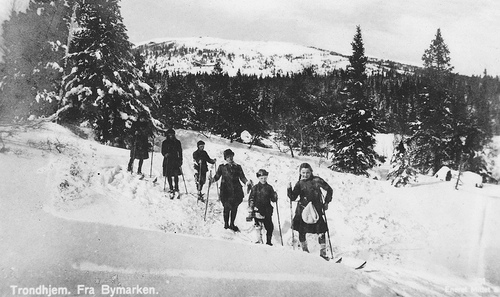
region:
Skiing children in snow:
[127, 110, 342, 258]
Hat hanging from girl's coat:
[300, 203, 317, 224]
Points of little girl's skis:
[327, 256, 369, 268]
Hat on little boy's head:
[252, 168, 272, 178]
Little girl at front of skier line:
[288, 164, 341, 256]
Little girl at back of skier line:
[122, 107, 151, 180]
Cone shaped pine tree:
[330, 24, 382, 180]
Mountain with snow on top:
[137, 40, 440, 131]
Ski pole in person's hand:
[203, 166, 215, 219]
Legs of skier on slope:
[221, 205, 238, 229]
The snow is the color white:
[352, 178, 451, 263]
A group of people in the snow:
[108, 102, 379, 259]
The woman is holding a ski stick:
[281, 177, 305, 246]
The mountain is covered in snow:
[141, 18, 356, 80]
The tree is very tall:
[2, 0, 155, 145]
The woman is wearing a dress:
[282, 158, 338, 242]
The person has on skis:
[120, 163, 165, 188]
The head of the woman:
[294, 158, 314, 182]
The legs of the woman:
[288, 207, 328, 264]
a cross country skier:
[288, 163, 345, 263]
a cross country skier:
[247, 169, 284, 244]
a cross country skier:
[202, 148, 252, 232]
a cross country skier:
[189, 138, 219, 203]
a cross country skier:
[158, 129, 189, 200]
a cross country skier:
[124, 109, 156, 177]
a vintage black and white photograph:
[0, 1, 498, 293]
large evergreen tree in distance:
[328, 25, 381, 175]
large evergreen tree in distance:
[400, 26, 489, 175]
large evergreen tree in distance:
[0, 0, 165, 151]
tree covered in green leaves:
[324, 20, 390, 170]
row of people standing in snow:
[93, 108, 370, 257]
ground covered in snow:
[0, 210, 172, 295]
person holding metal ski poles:
[279, 157, 349, 267]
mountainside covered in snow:
[140, 30, 330, 77]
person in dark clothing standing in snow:
[205, 138, 249, 243]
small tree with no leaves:
[448, 145, 473, 196]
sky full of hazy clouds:
[147, 0, 329, 38]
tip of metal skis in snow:
[332, 243, 379, 277]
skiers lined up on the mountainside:
[120, 102, 350, 259]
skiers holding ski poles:
[127, 104, 339, 273]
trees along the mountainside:
[8, 10, 488, 192]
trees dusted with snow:
[26, 14, 478, 180]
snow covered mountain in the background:
[136, 35, 454, 78]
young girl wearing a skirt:
[283, 167, 355, 262]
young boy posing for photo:
[248, 171, 298, 242]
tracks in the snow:
[76, 141, 416, 296]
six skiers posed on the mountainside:
[122, 96, 359, 273]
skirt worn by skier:
[293, 206, 325, 232]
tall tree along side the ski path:
[330, 23, 388, 173]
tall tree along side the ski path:
[2, 1, 141, 148]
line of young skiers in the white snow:
[123, 108, 367, 268]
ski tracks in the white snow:
[16, 127, 497, 293]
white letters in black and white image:
[7, 281, 162, 296]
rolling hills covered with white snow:
[130, 34, 410, 77]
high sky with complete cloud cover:
[112, 1, 499, 81]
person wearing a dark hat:
[207, 149, 247, 235]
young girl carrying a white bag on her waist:
[287, 164, 334, 261]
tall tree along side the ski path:
[392, 26, 498, 193]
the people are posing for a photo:
[102, 91, 394, 293]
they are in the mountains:
[95, 77, 392, 294]